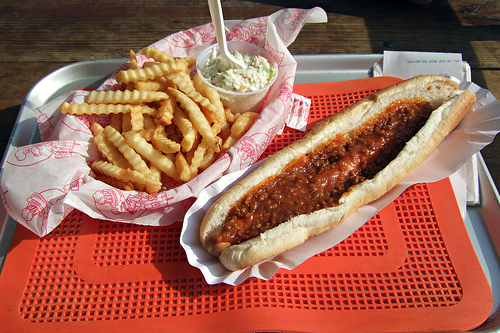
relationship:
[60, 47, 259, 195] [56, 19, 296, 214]
french fry inside basket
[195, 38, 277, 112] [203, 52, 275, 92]
container has cole slaw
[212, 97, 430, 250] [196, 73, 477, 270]
hot dog on a bun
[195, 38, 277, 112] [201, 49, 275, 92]
container with cole slaw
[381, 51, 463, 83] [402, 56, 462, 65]
receipt with black text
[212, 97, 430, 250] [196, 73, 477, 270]
hot dog with bun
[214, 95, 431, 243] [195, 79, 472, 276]
chili on hot dog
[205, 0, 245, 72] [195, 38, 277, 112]
fork in container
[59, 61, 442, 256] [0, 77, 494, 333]
food on a place mat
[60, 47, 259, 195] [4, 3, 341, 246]
french fry in basket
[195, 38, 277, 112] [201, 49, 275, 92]
container of cole slaw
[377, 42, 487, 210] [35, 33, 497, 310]
receipt on tray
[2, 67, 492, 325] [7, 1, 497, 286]
mat under food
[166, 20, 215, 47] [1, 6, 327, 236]
pattern on paper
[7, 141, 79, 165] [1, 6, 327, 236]
pattern on paper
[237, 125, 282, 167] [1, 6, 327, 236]
pattern on paper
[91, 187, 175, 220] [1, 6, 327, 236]
pattern on paper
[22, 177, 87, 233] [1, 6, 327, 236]
pattern on paper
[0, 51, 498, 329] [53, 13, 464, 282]
tray to carry food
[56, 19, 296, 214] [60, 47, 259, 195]
basket of french fry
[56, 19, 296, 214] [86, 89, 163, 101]
basket of fry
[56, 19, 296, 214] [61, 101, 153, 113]
basket of fry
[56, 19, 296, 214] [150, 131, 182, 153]
basket of fry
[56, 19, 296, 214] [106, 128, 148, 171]
basket of fry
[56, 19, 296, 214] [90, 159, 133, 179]
basket of fry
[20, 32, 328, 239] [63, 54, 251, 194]
basket of fries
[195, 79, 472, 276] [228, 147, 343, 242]
hot dog with chili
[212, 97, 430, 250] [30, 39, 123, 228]
hot dog on paper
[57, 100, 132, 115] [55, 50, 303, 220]
french fry in bowl